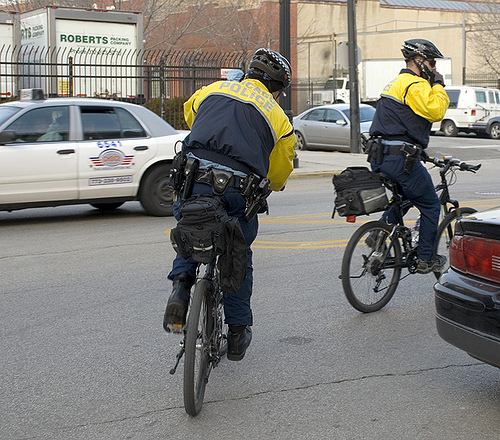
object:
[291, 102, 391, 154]
car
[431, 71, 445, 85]
hand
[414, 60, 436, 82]
phone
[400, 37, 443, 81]
head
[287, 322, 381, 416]
road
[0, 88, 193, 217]
car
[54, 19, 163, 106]
door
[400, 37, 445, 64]
helmet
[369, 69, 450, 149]
jacket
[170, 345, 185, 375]
stand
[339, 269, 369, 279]
stand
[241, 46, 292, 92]
helmet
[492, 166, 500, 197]
ground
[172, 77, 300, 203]
jacket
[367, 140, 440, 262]
pants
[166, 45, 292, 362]
he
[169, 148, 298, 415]
bike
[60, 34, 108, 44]
roberts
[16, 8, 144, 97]
truck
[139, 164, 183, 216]
shirt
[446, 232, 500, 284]
light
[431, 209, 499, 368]
back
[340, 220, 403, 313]
tire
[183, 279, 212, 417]
tire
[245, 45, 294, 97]
man's head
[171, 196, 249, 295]
bag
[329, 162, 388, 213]
bag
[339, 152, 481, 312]
bike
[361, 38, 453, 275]
he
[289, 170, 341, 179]
curb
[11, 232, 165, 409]
road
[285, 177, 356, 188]
edge